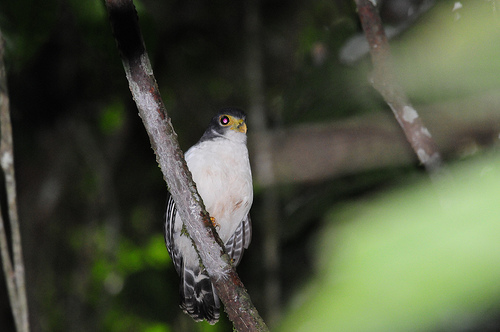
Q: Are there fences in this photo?
A: No, there are no fences.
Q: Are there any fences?
A: No, there are no fences.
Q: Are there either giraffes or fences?
A: No, there are no fences or giraffes.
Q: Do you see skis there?
A: No, there are no skis.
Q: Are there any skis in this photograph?
A: No, there are no skis.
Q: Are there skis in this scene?
A: No, there are no skis.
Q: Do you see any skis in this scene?
A: No, there are no skis.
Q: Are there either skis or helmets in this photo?
A: No, there are no skis or helmets.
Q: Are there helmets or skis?
A: No, there are no skis or helmets.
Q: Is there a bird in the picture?
A: Yes, there is a bird.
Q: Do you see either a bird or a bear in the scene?
A: Yes, there is a bird.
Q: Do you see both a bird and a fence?
A: No, there is a bird but no fences.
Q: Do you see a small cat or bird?
A: Yes, there is a small bird.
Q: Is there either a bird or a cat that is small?
A: Yes, the bird is small.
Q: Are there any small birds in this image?
A: Yes, there is a small bird.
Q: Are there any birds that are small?
A: Yes, there is a bird that is small.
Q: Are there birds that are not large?
A: Yes, there is a small bird.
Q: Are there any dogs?
A: No, there are no dogs.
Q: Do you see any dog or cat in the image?
A: No, there are no dogs or cats.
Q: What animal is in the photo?
A: The animal is a bird.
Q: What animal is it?
A: The animal is a bird.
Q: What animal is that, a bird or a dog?
A: This is a bird.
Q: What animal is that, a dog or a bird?
A: This is a bird.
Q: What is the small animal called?
A: The animal is a bird.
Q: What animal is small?
A: The animal is a bird.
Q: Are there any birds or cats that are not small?
A: No, there is a bird but it is small.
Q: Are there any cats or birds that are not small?
A: No, there is a bird but it is small.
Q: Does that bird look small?
A: Yes, the bird is small.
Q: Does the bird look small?
A: Yes, the bird is small.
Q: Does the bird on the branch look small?
A: Yes, the bird is small.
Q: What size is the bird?
A: The bird is small.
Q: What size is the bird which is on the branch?
A: The bird is small.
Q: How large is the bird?
A: The bird is small.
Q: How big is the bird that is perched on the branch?
A: The bird is small.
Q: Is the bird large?
A: No, the bird is small.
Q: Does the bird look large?
A: No, the bird is small.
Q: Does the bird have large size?
A: No, the bird is small.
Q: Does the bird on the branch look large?
A: No, the bird is small.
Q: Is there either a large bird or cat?
A: No, there is a bird but it is small.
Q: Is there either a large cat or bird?
A: No, there is a bird but it is small.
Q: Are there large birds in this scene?
A: No, there is a bird but it is small.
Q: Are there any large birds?
A: No, there is a bird but it is small.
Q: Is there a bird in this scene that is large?
A: No, there is a bird but it is small.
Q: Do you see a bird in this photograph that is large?
A: No, there is a bird but it is small.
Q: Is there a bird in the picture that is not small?
A: No, there is a bird but it is small.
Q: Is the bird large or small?
A: The bird is small.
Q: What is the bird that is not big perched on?
A: The bird is perched on the branch.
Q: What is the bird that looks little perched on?
A: The bird is perched on the branch.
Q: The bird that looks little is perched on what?
A: The bird is perched on the branch.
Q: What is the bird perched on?
A: The bird is perched on the branch.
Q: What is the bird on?
A: The bird is on the branch.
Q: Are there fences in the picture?
A: No, there are no fences.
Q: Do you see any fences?
A: No, there are no fences.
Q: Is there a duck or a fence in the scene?
A: No, there are no fences or ducks.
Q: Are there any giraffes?
A: No, there are no giraffes.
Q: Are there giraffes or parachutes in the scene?
A: No, there are no giraffes or parachutes.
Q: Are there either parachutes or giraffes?
A: No, there are no giraffes or parachutes.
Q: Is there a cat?
A: No, there are no cats.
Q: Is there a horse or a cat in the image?
A: No, there are no cats or horses.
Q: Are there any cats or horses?
A: No, there are no cats or horses.